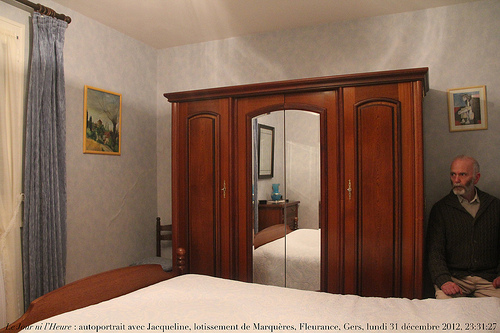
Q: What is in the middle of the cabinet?
A: Mirrors.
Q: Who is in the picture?
A: A man.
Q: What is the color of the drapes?
A: Blue.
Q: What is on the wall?
A: Pictures.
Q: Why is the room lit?
A: The light is on.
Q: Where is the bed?
A: In the middle of the room.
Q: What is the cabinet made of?
A: Wood.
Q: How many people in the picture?
A: One.